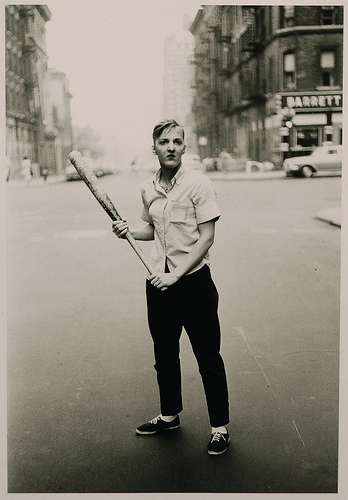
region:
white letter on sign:
[287, 97, 295, 108]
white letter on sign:
[294, 95, 301, 107]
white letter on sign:
[302, 94, 309, 106]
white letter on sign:
[310, 95, 318, 108]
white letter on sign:
[318, 96, 325, 105]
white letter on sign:
[324, 93, 331, 106]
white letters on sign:
[283, 96, 340, 106]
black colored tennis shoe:
[205, 429, 230, 456]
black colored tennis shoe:
[134, 415, 182, 434]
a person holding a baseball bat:
[67, 119, 233, 454]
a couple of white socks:
[159, 414, 225, 432]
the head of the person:
[151, 121, 186, 172]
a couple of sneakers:
[134, 419, 233, 455]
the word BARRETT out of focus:
[285, 95, 340, 107]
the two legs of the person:
[136, 297, 231, 453]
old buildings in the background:
[6, 8, 337, 105]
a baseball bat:
[67, 150, 165, 289]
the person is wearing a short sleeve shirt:
[139, 165, 220, 279]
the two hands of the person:
[113, 218, 175, 289]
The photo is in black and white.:
[46, 20, 326, 318]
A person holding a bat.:
[65, 155, 155, 286]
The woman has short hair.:
[145, 121, 177, 138]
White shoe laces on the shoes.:
[128, 408, 241, 444]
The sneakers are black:
[192, 426, 242, 457]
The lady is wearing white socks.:
[149, 403, 227, 433]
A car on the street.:
[267, 116, 345, 186]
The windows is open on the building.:
[264, 42, 338, 88]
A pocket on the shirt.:
[164, 199, 195, 226]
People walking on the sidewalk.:
[20, 148, 55, 182]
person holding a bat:
[64, 106, 266, 458]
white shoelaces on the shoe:
[208, 428, 228, 445]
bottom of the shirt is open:
[158, 256, 175, 277]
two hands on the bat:
[66, 150, 184, 298]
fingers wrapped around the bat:
[110, 216, 133, 241]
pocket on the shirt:
[166, 199, 190, 227]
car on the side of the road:
[274, 134, 343, 179]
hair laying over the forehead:
[161, 121, 181, 137]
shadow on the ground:
[18, 446, 337, 492]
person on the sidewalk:
[20, 155, 36, 186]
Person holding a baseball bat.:
[66, 91, 227, 302]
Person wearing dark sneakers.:
[131, 401, 233, 460]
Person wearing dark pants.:
[140, 245, 235, 419]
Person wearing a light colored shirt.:
[136, 160, 221, 281]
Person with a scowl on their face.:
[149, 115, 195, 178]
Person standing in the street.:
[133, 103, 251, 462]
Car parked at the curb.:
[282, 137, 341, 180]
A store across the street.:
[267, 91, 343, 158]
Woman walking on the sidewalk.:
[17, 146, 33, 184]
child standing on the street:
[156, 130, 197, 316]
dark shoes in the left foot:
[208, 425, 224, 455]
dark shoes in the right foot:
[139, 412, 177, 435]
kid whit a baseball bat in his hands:
[86, 131, 191, 272]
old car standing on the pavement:
[288, 150, 336, 178]